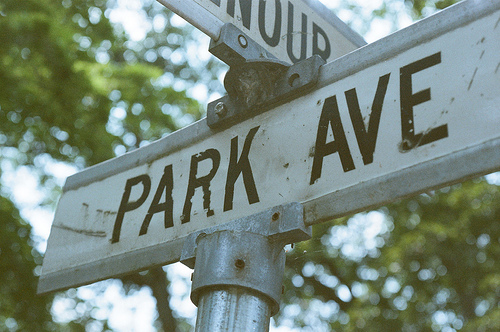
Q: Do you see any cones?
A: No, there are no cones.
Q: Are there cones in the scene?
A: No, there are no cones.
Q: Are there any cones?
A: No, there are no cones.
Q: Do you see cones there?
A: No, there are no cones.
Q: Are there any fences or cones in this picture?
A: No, there are no cones or fences.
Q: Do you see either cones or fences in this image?
A: No, there are no cones or fences.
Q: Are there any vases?
A: No, there are no vases.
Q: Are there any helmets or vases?
A: No, there are no vases or helmets.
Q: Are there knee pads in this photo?
A: No, there are no knee pads.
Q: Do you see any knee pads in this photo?
A: No, there are no knee pads.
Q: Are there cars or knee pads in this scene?
A: No, there are no knee pads or cars.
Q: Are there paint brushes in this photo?
A: No, there are no paint brushes.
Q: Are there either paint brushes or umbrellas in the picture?
A: No, there are no paint brushes or umbrellas.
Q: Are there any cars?
A: No, there are no cars.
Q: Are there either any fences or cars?
A: No, there are no cars or fences.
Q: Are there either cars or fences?
A: No, there are no cars or fences.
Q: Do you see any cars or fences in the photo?
A: No, there are no cars or fences.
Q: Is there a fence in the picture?
A: No, there are no fences.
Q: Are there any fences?
A: No, there are no fences.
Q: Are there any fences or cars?
A: No, there are no fences or cars.